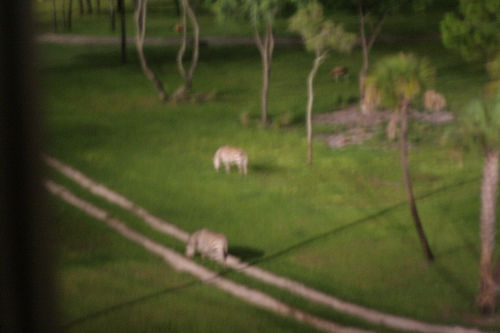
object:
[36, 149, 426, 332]
path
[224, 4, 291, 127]
tree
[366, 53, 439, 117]
leaves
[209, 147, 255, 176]
animal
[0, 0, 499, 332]
field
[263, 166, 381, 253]
grass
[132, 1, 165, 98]
trunk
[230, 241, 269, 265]
shadow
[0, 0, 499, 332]
ground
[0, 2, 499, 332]
picture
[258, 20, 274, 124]
logs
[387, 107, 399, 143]
logs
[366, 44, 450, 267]
tree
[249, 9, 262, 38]
twig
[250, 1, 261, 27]
small twig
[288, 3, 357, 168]
tree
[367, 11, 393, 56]
branches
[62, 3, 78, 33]
tree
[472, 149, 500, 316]
tree